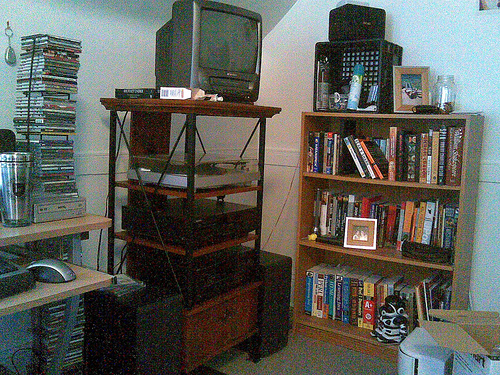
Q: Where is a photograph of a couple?
A: On the middle shelf, in front of the books.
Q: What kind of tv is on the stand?
A: Old one.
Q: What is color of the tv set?
A: Gray.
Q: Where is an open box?
A: In the lower right corner.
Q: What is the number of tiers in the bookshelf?
A: Three.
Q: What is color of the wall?
A: Blue.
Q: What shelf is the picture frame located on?
A: The second shelf.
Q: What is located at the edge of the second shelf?
A: A flashlight.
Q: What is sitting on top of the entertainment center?
A: A television.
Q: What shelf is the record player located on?
A: The second shelf.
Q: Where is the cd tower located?
A: On the desk.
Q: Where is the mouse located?
A: Below the cd tower, on the shelf.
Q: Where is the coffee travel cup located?
A: Next to the cd tower.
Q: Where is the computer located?
A: On the floor.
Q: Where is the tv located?
A: On the top shelf.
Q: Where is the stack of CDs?
A: On a shelf.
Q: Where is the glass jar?
A: On the top shelf of the bookcase.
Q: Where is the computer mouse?
A: On the desk.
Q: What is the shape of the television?
A: Square.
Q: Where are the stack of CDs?
A: On the desk.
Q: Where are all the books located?
A: On the bookshelf.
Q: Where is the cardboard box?
A: To the side of the bookcase.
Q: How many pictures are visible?
A: Two.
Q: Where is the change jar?
A: On the top corner of the bookshelf.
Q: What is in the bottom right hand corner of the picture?
A: A box.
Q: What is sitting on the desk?
A: A cup and a dvd rom/player.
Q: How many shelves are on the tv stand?
A: Four.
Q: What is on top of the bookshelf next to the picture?
A: A black crate.